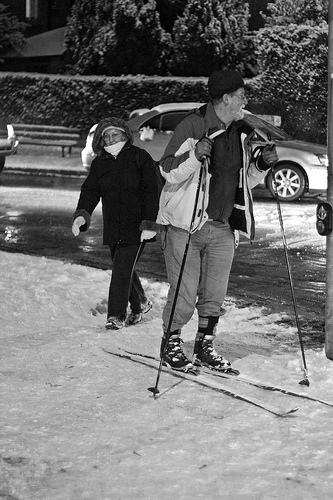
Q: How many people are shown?
A: Two.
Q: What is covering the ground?
A: Snow.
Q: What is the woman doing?
A: Walking.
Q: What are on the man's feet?
A: Skis.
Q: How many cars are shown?
A: One.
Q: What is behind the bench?
A: Shrubs.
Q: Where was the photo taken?
A: Near road.